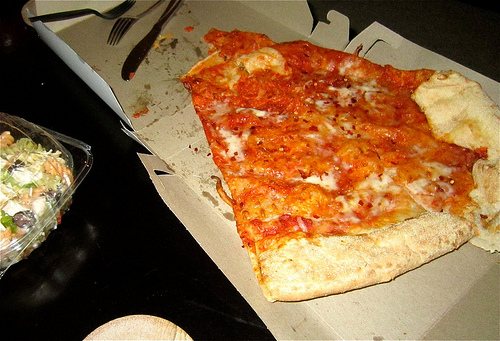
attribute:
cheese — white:
[181, 26, 487, 251]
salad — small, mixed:
[0, 127, 75, 266]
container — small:
[0, 110, 91, 273]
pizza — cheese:
[167, 30, 498, 271]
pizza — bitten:
[192, 22, 497, 300]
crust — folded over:
[411, 67, 498, 175]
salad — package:
[1, 130, 68, 248]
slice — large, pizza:
[178, 27, 498, 302]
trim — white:
[31, 16, 131, 127]